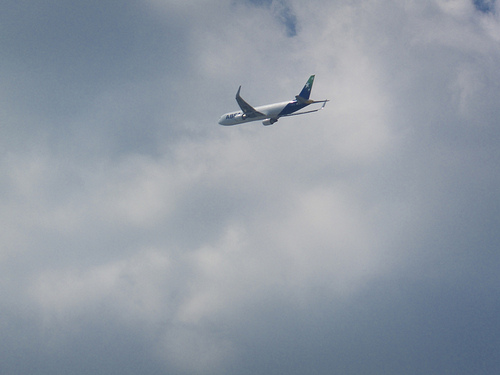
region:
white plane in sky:
[199, 65, 331, 135]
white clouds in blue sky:
[38, 125, 113, 196]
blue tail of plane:
[297, 74, 322, 100]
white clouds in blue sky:
[140, 276, 215, 330]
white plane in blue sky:
[207, 75, 334, 129]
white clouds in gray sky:
[264, 238, 354, 306]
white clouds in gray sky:
[42, 31, 113, 89]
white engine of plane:
[260, 115, 282, 128]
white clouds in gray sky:
[116, 251, 171, 281]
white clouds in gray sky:
[293, 253, 348, 300]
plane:
[205, 73, 332, 130]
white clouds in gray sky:
[126, 200, 200, 245]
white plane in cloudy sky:
[208, 68, 335, 137]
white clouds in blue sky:
[179, 191, 246, 247]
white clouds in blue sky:
[98, 50, 148, 99]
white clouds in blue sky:
[269, 8, 307, 35]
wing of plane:
[229, 80, 256, 110]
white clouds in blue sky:
[103, 252, 173, 294]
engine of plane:
[233, 103, 253, 123]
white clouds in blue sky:
[137, 243, 194, 288]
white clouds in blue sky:
[345, 219, 437, 269]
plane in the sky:
[215, 83, 335, 136]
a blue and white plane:
[205, 79, 348, 136]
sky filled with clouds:
[41, 132, 435, 342]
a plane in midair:
[207, 79, 342, 137]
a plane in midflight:
[192, 70, 349, 122]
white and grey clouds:
[48, 157, 470, 332]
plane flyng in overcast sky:
[197, 50, 374, 142]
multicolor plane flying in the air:
[211, 69, 328, 148]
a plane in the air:
[207, 75, 346, 150]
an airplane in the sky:
[216, 63, 333, 131]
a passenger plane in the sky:
[214, 62, 348, 147]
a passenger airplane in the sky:
[212, 63, 335, 148]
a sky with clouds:
[2, 1, 494, 366]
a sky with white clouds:
[8, 10, 498, 370]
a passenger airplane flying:
[214, 72, 379, 151]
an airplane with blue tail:
[216, 53, 311, 140]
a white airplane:
[194, 67, 358, 133]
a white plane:
[187, 48, 322, 140]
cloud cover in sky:
[2, 3, 497, 373]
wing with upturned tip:
[235, 86, 262, 118]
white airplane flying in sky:
[214, 73, 331, 129]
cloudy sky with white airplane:
[3, 5, 493, 367]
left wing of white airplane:
[234, 86, 266, 119]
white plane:
[198, 59, 340, 134]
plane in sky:
[199, 36, 334, 130]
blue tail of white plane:
[287, 76, 324, 98]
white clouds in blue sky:
[345, 266, 404, 329]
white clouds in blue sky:
[117, 113, 162, 155]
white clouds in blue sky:
[392, 69, 443, 140]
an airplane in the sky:
[215, 69, 334, 131]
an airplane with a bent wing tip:
[215, 72, 335, 130]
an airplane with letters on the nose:
[215, 72, 330, 132]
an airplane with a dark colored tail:
[212, 69, 331, 132]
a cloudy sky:
[8, 8, 492, 374]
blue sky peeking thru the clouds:
[277, 13, 303, 42]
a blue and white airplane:
[215, 71, 333, 132]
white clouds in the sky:
[17, 20, 399, 365]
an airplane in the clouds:
[214, 69, 335, 139]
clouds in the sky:
[108, 172, 282, 299]